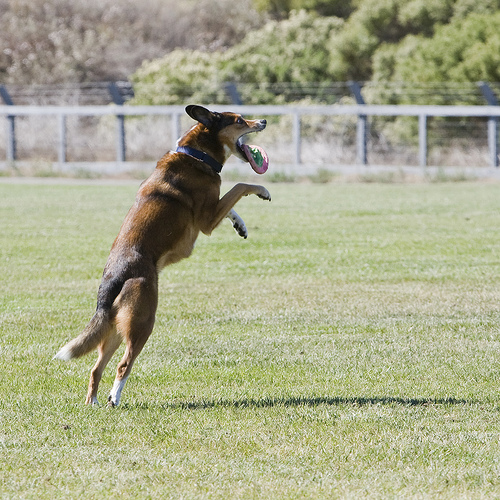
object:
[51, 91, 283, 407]
dog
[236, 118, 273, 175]
mouth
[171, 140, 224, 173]
collar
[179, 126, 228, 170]
neck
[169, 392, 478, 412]
shadow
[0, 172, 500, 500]
grass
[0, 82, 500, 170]
fence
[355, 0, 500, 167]
trees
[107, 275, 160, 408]
hind legs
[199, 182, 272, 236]
front legs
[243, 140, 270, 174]
frisbee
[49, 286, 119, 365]
tail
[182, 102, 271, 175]
head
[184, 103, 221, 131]
ears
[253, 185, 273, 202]
paws